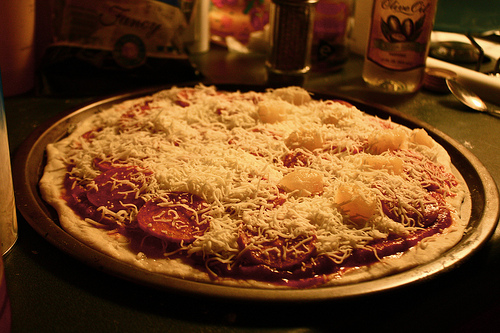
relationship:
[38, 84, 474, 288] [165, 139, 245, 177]
frozen pizza has cheese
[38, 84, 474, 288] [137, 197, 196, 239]
frozen pizza has pepperoni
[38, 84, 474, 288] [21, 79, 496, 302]
frozen pizza on tray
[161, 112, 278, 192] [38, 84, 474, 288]
cheese on frozen pizza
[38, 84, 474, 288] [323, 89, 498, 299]
frozen pizza inside platter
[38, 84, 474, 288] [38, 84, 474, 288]
frozen pizza on frozen pizza